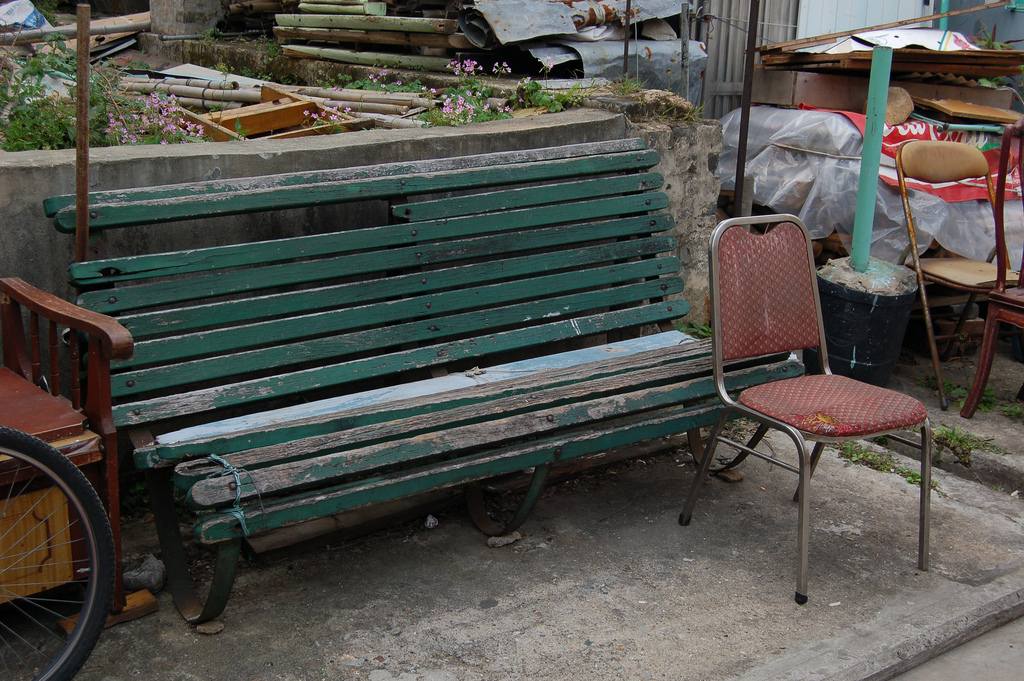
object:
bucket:
[814, 252, 920, 389]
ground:
[792, 276, 857, 345]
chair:
[0, 277, 156, 633]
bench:
[44, 137, 811, 628]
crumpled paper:
[425, 514, 438, 528]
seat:
[808, 405, 854, 436]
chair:
[706, 213, 933, 605]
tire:
[0, 427, 118, 677]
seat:
[737, 372, 928, 438]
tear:
[808, 413, 836, 428]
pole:
[76, 4, 92, 266]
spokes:
[0, 487, 76, 605]